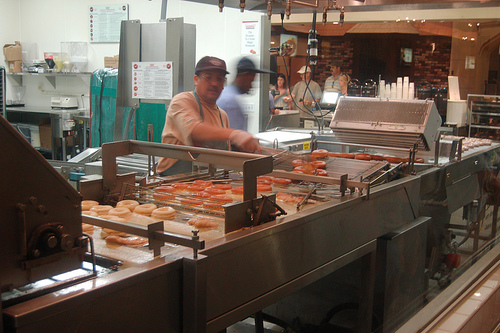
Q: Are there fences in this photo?
A: No, there are no fences.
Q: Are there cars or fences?
A: No, there are no fences or cars.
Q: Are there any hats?
A: Yes, there is a hat.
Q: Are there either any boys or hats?
A: Yes, there is a hat.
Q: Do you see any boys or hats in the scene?
A: Yes, there is a hat.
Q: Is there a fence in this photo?
A: No, there are no fences.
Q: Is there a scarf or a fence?
A: No, there are no fences or scarves.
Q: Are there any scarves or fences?
A: No, there are no fences or scarves.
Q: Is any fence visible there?
A: No, there are no fences.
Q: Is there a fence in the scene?
A: No, there are no fences.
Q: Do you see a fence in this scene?
A: No, there are no fences.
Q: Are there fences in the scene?
A: No, there are no fences.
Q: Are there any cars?
A: No, there are no cars.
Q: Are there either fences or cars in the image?
A: No, there are no cars or fences.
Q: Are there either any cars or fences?
A: No, there are no cars or fences.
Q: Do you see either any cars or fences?
A: No, there are no cars or fences.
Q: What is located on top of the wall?
A: The sign is on top of the wall.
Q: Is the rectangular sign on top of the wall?
A: Yes, the sign is on top of the wall.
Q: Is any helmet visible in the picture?
A: No, there are no helmets.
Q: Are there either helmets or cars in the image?
A: No, there are no helmets or cars.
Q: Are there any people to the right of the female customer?
A: Yes, there is a person to the right of the customer.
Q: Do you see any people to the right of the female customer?
A: Yes, there is a person to the right of the customer.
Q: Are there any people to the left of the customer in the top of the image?
A: No, the person is to the right of the customer.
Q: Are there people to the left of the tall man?
A: Yes, there is a person to the left of the man.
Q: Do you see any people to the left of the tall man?
A: Yes, there is a person to the left of the man.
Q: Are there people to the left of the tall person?
A: Yes, there is a person to the left of the man.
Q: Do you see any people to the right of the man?
A: No, the person is to the left of the man.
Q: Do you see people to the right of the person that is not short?
A: No, the person is to the left of the man.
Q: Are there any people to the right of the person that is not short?
A: No, the person is to the left of the man.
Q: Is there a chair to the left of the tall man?
A: No, there is a person to the left of the man.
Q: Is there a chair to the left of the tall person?
A: No, there is a person to the left of the man.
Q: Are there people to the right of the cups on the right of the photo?
A: No, the person is to the left of the cups.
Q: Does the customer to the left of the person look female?
A: Yes, the customer is female.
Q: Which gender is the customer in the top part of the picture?
A: The customer is female.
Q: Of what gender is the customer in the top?
A: The customer is female.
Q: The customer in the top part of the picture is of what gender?
A: The customer is female.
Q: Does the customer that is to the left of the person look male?
A: No, the customer is female.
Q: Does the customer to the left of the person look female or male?
A: The customer is female.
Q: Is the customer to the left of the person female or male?
A: The customer is female.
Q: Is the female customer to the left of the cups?
A: Yes, the customer is to the left of the cups.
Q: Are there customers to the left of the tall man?
A: Yes, there is a customer to the left of the man.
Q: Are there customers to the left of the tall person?
A: Yes, there is a customer to the left of the man.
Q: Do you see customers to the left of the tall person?
A: Yes, there is a customer to the left of the man.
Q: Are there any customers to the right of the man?
A: No, the customer is to the left of the man.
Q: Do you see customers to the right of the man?
A: No, the customer is to the left of the man.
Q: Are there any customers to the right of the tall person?
A: No, the customer is to the left of the man.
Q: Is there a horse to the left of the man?
A: No, there is a customer to the left of the man.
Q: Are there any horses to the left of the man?
A: No, there is a customer to the left of the man.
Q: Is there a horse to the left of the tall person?
A: No, there is a customer to the left of the man.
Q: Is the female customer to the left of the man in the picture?
A: Yes, the customer is to the left of the man.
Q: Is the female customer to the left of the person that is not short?
A: Yes, the customer is to the left of the man.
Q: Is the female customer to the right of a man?
A: No, the customer is to the left of a man.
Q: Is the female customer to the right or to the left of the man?
A: The customer is to the left of the man.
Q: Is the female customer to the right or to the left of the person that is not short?
A: The customer is to the left of the man.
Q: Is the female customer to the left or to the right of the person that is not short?
A: The customer is to the left of the man.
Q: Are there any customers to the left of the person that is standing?
A: Yes, there is a customer to the left of the person.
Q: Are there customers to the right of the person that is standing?
A: No, the customer is to the left of the person.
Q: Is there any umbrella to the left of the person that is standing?
A: No, there is a customer to the left of the person.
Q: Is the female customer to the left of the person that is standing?
A: Yes, the customer is to the left of the person.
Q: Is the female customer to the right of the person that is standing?
A: No, the customer is to the left of the person.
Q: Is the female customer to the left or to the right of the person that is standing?
A: The customer is to the left of the person.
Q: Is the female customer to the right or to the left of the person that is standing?
A: The customer is to the left of the person.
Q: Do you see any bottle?
A: No, there are no bottles.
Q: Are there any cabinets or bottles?
A: No, there are no bottles or cabinets.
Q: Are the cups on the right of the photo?
A: Yes, the cups are on the right of the image.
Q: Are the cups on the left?
A: No, the cups are on the right of the image.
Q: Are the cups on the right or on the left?
A: The cups are on the right of the image.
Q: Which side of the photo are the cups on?
A: The cups are on the right of the image.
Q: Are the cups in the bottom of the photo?
A: No, the cups are in the top of the image.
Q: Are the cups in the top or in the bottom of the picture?
A: The cups are in the top of the image.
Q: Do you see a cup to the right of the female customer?
A: Yes, there are cups to the right of the customer.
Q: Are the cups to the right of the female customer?
A: Yes, the cups are to the right of the customer.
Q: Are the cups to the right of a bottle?
A: No, the cups are to the right of the customer.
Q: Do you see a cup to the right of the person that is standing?
A: Yes, there are cups to the right of the person.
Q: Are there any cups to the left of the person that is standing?
A: No, the cups are to the right of the person.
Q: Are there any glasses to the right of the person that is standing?
A: No, there are cups to the right of the person.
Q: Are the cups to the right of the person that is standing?
A: Yes, the cups are to the right of the person.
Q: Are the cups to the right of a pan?
A: No, the cups are to the right of the person.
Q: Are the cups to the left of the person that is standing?
A: No, the cups are to the right of the person.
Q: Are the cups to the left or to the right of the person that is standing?
A: The cups are to the right of the person.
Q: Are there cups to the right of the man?
A: Yes, there are cups to the right of the man.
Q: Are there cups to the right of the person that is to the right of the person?
A: Yes, there are cups to the right of the man.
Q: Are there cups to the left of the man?
A: No, the cups are to the right of the man.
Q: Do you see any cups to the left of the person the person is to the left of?
A: No, the cups are to the right of the man.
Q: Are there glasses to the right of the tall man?
A: No, there are cups to the right of the man.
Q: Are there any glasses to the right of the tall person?
A: No, there are cups to the right of the man.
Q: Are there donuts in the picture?
A: Yes, there are donuts.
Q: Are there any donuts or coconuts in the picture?
A: Yes, there are donuts.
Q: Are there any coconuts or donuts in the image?
A: Yes, there are donuts.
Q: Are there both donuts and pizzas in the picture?
A: No, there are donuts but no pizzas.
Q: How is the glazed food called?
A: The food is donuts.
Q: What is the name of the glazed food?
A: The food is donuts.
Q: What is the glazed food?
A: The food is donuts.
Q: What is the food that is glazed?
A: The food is donuts.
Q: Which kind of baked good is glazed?
A: The baked good is donuts.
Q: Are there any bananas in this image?
A: No, there are no bananas.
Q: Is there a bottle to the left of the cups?
A: No, there is a customer to the left of the cups.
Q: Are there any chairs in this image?
A: No, there are no chairs.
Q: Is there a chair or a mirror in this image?
A: No, there are no chairs or mirrors.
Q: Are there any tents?
A: No, there are no tents.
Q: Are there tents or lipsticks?
A: No, there are no tents or lipsticks.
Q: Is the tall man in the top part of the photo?
A: Yes, the man is in the top of the image.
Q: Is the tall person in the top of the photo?
A: Yes, the man is in the top of the image.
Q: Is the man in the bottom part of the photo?
A: No, the man is in the top of the image.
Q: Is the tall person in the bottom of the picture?
A: No, the man is in the top of the image.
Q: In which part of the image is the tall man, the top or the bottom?
A: The man is in the top of the image.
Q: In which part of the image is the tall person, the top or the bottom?
A: The man is in the top of the image.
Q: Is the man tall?
A: Yes, the man is tall.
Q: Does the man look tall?
A: Yes, the man is tall.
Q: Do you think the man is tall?
A: Yes, the man is tall.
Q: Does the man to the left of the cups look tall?
A: Yes, the man is tall.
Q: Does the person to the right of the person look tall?
A: Yes, the man is tall.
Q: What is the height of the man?
A: The man is tall.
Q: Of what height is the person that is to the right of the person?
A: The man is tall.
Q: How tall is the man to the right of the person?
A: The man is tall.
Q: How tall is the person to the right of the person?
A: The man is tall.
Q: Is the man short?
A: No, the man is tall.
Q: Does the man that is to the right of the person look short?
A: No, the man is tall.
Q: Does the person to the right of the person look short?
A: No, the man is tall.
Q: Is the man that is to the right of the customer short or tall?
A: The man is tall.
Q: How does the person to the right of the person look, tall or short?
A: The man is tall.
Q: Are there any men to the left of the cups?
A: Yes, there is a man to the left of the cups.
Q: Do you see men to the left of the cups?
A: Yes, there is a man to the left of the cups.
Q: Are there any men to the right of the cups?
A: No, the man is to the left of the cups.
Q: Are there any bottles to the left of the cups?
A: No, there is a man to the left of the cups.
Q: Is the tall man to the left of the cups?
A: Yes, the man is to the left of the cups.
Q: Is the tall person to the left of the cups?
A: Yes, the man is to the left of the cups.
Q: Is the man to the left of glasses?
A: No, the man is to the left of the cups.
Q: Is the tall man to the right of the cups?
A: No, the man is to the left of the cups.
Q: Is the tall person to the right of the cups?
A: No, the man is to the left of the cups.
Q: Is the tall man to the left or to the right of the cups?
A: The man is to the left of the cups.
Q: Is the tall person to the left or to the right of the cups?
A: The man is to the left of the cups.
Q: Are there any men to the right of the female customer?
A: Yes, there is a man to the right of the customer.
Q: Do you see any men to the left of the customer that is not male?
A: No, the man is to the right of the customer.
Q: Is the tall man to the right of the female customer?
A: Yes, the man is to the right of the customer.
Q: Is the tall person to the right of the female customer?
A: Yes, the man is to the right of the customer.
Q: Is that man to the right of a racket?
A: No, the man is to the right of the customer.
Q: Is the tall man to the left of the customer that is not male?
A: No, the man is to the right of the customer.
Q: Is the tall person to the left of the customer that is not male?
A: No, the man is to the right of the customer.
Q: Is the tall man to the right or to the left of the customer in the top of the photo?
A: The man is to the right of the customer.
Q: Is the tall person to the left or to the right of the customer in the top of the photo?
A: The man is to the right of the customer.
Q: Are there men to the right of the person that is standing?
A: Yes, there is a man to the right of the person.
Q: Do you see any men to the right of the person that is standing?
A: Yes, there is a man to the right of the person.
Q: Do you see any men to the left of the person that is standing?
A: No, the man is to the right of the person.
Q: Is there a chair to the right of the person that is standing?
A: No, there is a man to the right of the person.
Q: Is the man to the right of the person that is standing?
A: Yes, the man is to the right of the person.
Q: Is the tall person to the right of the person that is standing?
A: Yes, the man is to the right of the person.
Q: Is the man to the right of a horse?
A: No, the man is to the right of the person.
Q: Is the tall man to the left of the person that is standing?
A: No, the man is to the right of the person.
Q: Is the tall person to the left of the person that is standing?
A: No, the man is to the right of the person.